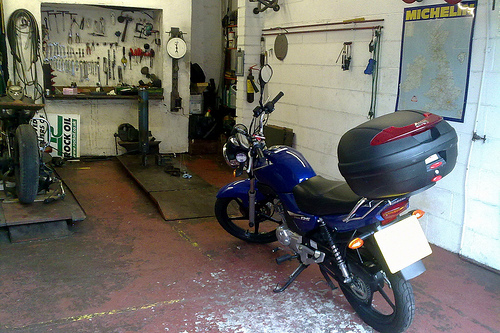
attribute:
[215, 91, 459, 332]
motorcycle — sideways, blue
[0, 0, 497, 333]
garage — object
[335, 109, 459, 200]
cargo container — black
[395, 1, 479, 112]
sign — michelin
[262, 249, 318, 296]
kickstand — object, black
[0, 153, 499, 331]
garage floor — painted, dirty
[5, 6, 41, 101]
wires — hanging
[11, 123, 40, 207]
tire — black, worn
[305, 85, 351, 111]
cement brick — white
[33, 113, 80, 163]
sign — green, white, business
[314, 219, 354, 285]
shock — rear, object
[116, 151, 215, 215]
lift — object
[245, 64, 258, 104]
fire extinguisher — object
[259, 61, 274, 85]
mirror — rear